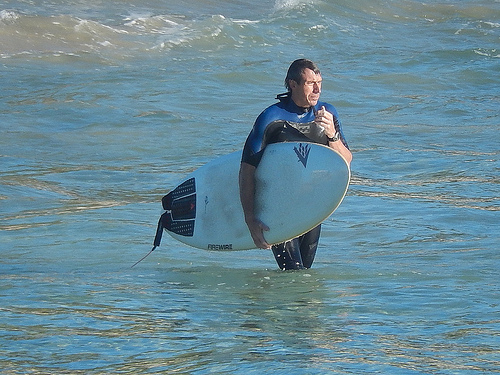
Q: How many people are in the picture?
A: One.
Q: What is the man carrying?
A: A surfboard.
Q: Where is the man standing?
A: In the water.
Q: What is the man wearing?
A: A wetsuit.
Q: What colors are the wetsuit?
A: Blue and black.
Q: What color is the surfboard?
A: White and black.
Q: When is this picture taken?
A: Daytime.